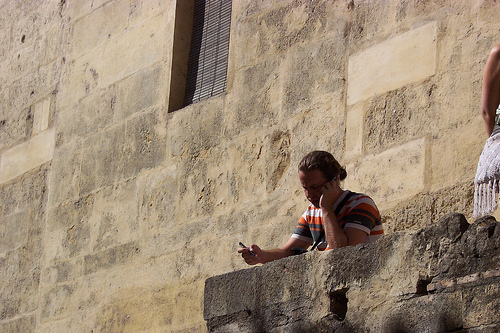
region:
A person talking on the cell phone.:
[321, 177, 362, 207]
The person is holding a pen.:
[235, 239, 265, 263]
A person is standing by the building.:
[451, 47, 497, 214]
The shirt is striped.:
[289, 205, 411, 248]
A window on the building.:
[148, 9, 253, 114]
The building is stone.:
[33, 104, 240, 322]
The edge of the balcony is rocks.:
[389, 214, 498, 271]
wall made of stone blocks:
[4, 3, 496, 326]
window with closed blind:
[169, 2, 234, 112]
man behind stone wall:
[205, 150, 382, 331]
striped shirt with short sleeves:
[293, 192, 383, 250]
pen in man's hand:
[238, 242, 269, 266]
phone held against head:
[316, 176, 343, 208]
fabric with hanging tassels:
[473, 137, 497, 217]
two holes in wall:
[327, 279, 437, 323]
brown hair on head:
[299, 152, 346, 179]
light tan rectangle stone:
[346, 20, 437, 100]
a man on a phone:
[250, 128, 380, 311]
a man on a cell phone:
[254, 151, 364, 275]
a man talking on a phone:
[276, 128, 437, 325]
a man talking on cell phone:
[244, 125, 374, 289]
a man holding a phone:
[296, 145, 422, 332]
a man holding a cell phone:
[289, 127, 425, 326]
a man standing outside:
[285, 158, 394, 318]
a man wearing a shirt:
[240, 118, 408, 331]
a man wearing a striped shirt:
[271, 147, 403, 255]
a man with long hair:
[285, 151, 415, 237]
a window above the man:
[170, 3, 237, 105]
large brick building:
[2, 2, 497, 327]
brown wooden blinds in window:
[188, 1, 230, 101]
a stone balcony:
[183, 213, 478, 328]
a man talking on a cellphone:
[237, 150, 383, 251]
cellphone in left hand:
[318, 175, 340, 207]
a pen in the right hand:
[237, 241, 262, 266]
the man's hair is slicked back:
[298, 153, 347, 178]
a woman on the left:
[471, 43, 498, 218]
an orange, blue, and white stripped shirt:
[290, 193, 382, 250]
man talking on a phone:
[233, 147, 392, 272]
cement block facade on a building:
[58, 127, 217, 309]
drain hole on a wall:
[316, 278, 356, 318]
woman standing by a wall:
[463, 40, 493, 237]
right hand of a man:
[233, 232, 270, 272]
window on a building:
[166, 4, 231, 109]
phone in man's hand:
[319, 166, 344, 193]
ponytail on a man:
[331, 158, 351, 180]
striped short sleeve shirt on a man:
[293, 191, 375, 246]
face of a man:
[291, 147, 349, 208]